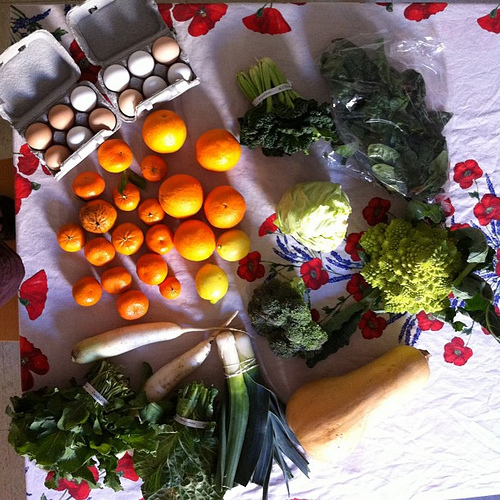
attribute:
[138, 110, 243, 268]
oranges — various, laid, many, round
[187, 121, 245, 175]
orange — round, yellow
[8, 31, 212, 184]
carton — open, gray, white, brown, white in color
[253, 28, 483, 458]
vegetables — green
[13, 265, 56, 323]
flower — red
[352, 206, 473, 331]
squash — large, orange, spiny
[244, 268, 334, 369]
brocolli — green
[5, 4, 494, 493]
foods — healthy, white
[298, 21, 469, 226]
leaves — green, clear, plastic, filled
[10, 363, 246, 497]
lettuce — small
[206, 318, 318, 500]
leeks — green, white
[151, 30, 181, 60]
egg — brown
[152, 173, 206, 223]
orange — small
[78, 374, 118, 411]
tag — white